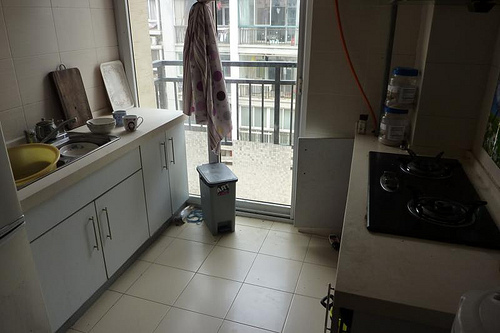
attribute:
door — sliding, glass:
[147, 0, 298, 224]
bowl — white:
[70, 110, 131, 141]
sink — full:
[6, 111, 161, 302]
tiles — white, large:
[153, 249, 306, 321]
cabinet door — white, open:
[295, 134, 355, 249]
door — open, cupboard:
[291, 136, 350, 232]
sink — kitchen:
[4, 105, 130, 220]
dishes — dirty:
[3, 89, 129, 196]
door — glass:
[227, 38, 307, 223]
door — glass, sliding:
[137, 0, 300, 214]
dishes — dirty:
[57, 135, 102, 160]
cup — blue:
[111, 107, 127, 129]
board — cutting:
[48, 61, 97, 132]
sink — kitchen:
[3, 124, 121, 194]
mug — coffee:
[120, 110, 146, 131]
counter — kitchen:
[5, 107, 182, 197]